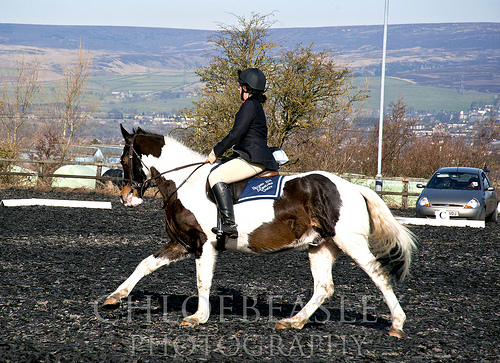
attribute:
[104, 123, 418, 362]
horse — white, brown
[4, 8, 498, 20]
day — daytime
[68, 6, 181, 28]
sky — blue